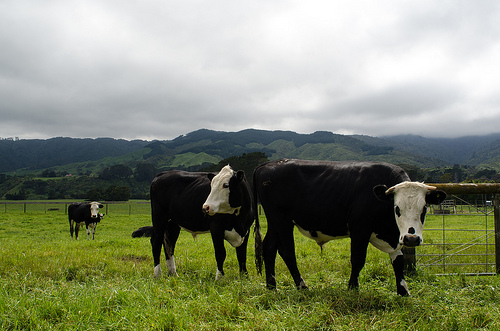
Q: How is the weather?
A: It is cloudy.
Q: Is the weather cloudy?
A: Yes, it is cloudy.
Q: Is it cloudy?
A: Yes, it is cloudy.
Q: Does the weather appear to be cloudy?
A: Yes, it is cloudy.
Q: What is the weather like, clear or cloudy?
A: It is cloudy.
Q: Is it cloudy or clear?
A: It is cloudy.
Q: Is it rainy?
A: No, it is cloudy.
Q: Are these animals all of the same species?
A: Yes, all the animals are cows.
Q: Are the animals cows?
A: Yes, all the animals are cows.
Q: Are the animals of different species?
A: No, all the animals are cows.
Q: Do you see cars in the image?
A: No, there are no cars.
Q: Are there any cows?
A: Yes, there is a cow.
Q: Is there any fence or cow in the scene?
A: Yes, there is a cow.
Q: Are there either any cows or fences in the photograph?
A: Yes, there is a cow.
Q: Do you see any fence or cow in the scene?
A: Yes, there is a cow.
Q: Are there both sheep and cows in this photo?
A: No, there is a cow but no sheep.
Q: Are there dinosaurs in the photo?
A: No, there are no dinosaurs.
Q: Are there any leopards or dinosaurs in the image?
A: No, there are no dinosaurs or leopards.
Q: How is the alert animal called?
A: The animal is a cow.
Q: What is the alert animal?
A: The animal is a cow.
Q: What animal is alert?
A: The animal is a cow.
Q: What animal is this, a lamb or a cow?
A: This is a cow.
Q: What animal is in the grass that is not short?
A: The animal is a cow.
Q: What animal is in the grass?
A: The animal is a cow.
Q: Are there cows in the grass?
A: Yes, there is a cow in the grass.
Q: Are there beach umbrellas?
A: No, there are no beach umbrellas.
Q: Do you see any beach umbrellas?
A: No, there are no beach umbrellas.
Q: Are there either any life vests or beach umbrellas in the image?
A: No, there are no beach umbrellas or life vests.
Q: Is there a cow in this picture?
A: Yes, there is a cow.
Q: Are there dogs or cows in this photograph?
A: Yes, there is a cow.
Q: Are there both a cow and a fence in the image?
A: Yes, there are both a cow and a fence.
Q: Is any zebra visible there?
A: No, there are no zebras.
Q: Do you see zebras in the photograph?
A: No, there are no zebras.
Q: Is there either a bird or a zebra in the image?
A: No, there are no zebras or birds.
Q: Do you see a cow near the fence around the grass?
A: Yes, there is a cow near the fence.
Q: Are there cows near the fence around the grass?
A: Yes, there is a cow near the fence.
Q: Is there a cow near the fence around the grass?
A: Yes, there is a cow near the fence.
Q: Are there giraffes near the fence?
A: No, there is a cow near the fence.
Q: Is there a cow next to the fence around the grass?
A: Yes, there is a cow next to the fence.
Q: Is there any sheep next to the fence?
A: No, there is a cow next to the fence.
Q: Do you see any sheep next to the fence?
A: No, there is a cow next to the fence.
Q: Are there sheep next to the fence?
A: No, there is a cow next to the fence.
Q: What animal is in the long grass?
A: The animal is a cow.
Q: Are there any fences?
A: Yes, there is a fence.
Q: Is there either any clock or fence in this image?
A: Yes, there is a fence.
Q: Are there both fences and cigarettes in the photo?
A: No, there is a fence but no cigarettes.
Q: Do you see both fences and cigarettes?
A: No, there is a fence but no cigarettes.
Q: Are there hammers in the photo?
A: No, there are no hammers.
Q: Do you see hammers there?
A: No, there are no hammers.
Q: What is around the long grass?
A: The fence is around the grass.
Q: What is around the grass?
A: The fence is around the grass.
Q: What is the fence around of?
A: The fence is around the grass.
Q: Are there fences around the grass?
A: Yes, there is a fence around the grass.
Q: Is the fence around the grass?
A: Yes, the fence is around the grass.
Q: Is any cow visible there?
A: Yes, there is a cow.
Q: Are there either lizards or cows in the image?
A: Yes, there is a cow.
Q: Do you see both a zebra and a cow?
A: No, there is a cow but no zebras.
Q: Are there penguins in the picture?
A: No, there are no penguins.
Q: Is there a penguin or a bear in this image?
A: No, there are no penguins or bears.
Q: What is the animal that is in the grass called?
A: The animal is a cow.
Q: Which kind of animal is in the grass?
A: The animal is a cow.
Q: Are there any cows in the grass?
A: Yes, there is a cow in the grass.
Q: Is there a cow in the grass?
A: Yes, there is a cow in the grass.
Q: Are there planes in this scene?
A: No, there are no planes.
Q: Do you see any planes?
A: No, there are no planes.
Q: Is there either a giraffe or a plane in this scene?
A: No, there are no airplanes or giraffes.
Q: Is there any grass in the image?
A: Yes, there is grass.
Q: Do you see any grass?
A: Yes, there is grass.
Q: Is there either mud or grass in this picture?
A: Yes, there is grass.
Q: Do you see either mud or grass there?
A: Yes, there is grass.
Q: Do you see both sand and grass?
A: No, there is grass but no sand.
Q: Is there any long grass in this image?
A: Yes, there is long grass.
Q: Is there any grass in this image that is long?
A: Yes, there is grass that is long.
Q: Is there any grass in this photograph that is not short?
A: Yes, there is long grass.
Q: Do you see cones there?
A: No, there are no cones.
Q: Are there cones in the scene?
A: No, there are no cones.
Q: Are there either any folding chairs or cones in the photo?
A: No, there are no cones or folding chairs.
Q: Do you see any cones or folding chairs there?
A: No, there are no cones or folding chairs.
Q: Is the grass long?
A: Yes, the grass is long.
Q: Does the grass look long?
A: Yes, the grass is long.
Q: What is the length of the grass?
A: The grass is long.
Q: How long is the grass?
A: The grass is long.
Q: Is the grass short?
A: No, the grass is long.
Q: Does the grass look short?
A: No, the grass is long.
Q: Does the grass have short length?
A: No, the grass is long.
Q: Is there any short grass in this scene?
A: No, there is grass but it is long.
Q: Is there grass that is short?
A: No, there is grass but it is long.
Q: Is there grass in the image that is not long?
A: No, there is grass but it is long.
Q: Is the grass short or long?
A: The grass is long.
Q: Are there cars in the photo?
A: No, there are no cars.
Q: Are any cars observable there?
A: No, there are no cars.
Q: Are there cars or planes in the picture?
A: No, there are no cars or planes.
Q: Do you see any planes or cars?
A: No, there are no cars or planes.